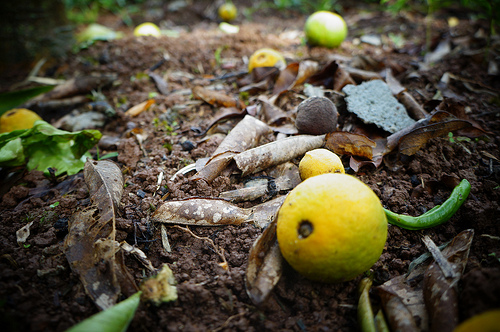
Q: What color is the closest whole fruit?
A: Yellow and green.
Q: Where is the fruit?
A: On the ground.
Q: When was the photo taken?
A: During the day.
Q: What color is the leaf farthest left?
A: Green.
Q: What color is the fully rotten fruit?
A: Grey.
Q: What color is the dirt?
A: Brown.